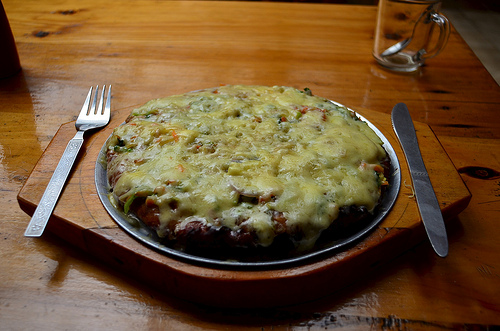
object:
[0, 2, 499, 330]
table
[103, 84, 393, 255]
pizza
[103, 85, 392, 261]
cheese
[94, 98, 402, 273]
pan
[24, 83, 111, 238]
fork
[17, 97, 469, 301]
board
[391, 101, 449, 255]
knife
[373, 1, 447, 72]
glass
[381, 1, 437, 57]
spoon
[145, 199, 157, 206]
tomato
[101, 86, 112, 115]
tines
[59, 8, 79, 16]
knot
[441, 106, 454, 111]
spot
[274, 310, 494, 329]
line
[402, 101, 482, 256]
edge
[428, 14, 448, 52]
handle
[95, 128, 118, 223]
edge